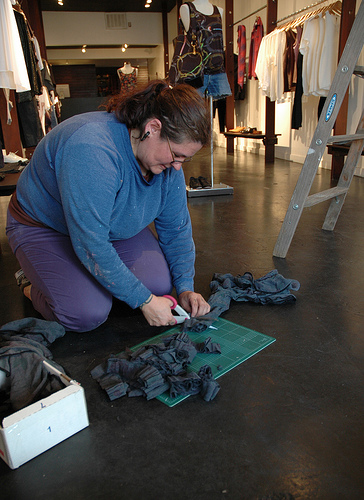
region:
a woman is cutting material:
[53, 133, 273, 390]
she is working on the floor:
[28, 149, 320, 389]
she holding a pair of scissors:
[145, 282, 216, 340]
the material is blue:
[122, 312, 220, 406]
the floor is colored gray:
[130, 410, 324, 484]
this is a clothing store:
[166, 42, 318, 144]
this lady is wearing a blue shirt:
[26, 98, 221, 271]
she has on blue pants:
[14, 219, 175, 327]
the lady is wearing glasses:
[162, 139, 197, 171]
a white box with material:
[7, 318, 90, 445]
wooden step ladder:
[268, 12, 362, 228]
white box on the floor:
[1, 382, 105, 473]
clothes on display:
[183, 1, 234, 93]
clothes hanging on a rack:
[254, 14, 340, 84]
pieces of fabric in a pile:
[105, 343, 223, 404]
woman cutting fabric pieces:
[164, 297, 227, 343]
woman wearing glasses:
[139, 110, 195, 195]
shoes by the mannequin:
[187, 174, 211, 191]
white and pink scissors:
[164, 294, 211, 337]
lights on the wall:
[77, 44, 127, 53]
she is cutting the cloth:
[152, 292, 224, 334]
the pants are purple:
[34, 243, 67, 269]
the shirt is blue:
[80, 158, 103, 189]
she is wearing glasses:
[167, 154, 193, 168]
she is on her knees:
[27, 260, 185, 330]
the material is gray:
[140, 357, 172, 375]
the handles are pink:
[163, 291, 177, 327]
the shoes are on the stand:
[189, 173, 212, 194]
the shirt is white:
[323, 33, 334, 60]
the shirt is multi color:
[197, 24, 214, 46]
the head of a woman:
[101, 42, 273, 170]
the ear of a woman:
[121, 102, 189, 151]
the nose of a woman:
[160, 150, 191, 182]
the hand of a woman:
[139, 288, 192, 332]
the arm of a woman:
[39, 82, 145, 325]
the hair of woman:
[88, 53, 255, 152]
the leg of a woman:
[3, 219, 181, 346]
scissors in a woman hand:
[139, 278, 233, 345]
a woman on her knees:
[52, 194, 267, 342]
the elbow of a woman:
[39, 157, 112, 283]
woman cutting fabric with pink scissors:
[5, 78, 226, 334]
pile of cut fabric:
[88, 317, 228, 410]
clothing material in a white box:
[3, 331, 89, 469]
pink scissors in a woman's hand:
[157, 294, 220, 329]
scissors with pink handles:
[154, 293, 219, 330]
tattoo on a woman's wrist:
[135, 296, 155, 312]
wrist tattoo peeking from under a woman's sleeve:
[132, 293, 154, 309]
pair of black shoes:
[188, 174, 211, 189]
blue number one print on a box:
[46, 426, 54, 432]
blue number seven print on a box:
[38, 402, 49, 407]